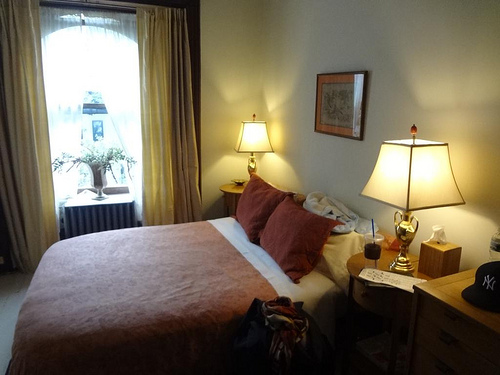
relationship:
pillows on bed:
[234, 174, 335, 273] [68, 173, 372, 356]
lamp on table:
[359, 95, 441, 278] [347, 244, 419, 354]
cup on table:
[363, 222, 387, 271] [347, 244, 419, 354]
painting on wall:
[309, 67, 375, 153] [277, 29, 402, 206]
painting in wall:
[309, 67, 375, 153] [277, 29, 402, 206]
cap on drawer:
[461, 263, 498, 315] [413, 284, 495, 372]